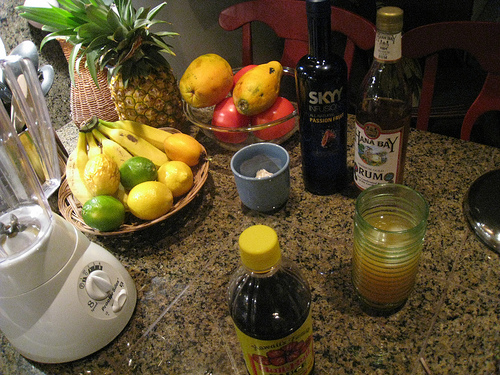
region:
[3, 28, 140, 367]
white blender with clear pitcher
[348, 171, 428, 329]
textured glass of orange juice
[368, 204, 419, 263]
ice cubes in orange juice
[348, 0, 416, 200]
glass bottle of rum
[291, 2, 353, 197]
bottle of SKYY brand vodka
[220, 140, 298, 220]
small cermic coffee mug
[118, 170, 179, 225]
yellow lemon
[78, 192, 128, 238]
green lime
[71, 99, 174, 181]
bunch of yellow bananas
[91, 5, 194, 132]
pineapple with green leaves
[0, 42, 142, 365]
a white electric blender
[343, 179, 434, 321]
a glass with drink and ice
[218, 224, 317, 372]
a plastic bottle with cap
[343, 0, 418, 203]
a bottle of alcohol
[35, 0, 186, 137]
a pineapple fruit with leaves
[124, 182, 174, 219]
a yellow lemon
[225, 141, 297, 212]
a blue ceramic cup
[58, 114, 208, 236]
a wicker basket of fruit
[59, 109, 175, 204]
a bunch of bananas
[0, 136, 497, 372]
a variegated granite countertop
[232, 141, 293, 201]
a small blug mug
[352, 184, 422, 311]
a greenish glass cup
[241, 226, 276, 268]
a yellow plastic top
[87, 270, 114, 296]
a white blender button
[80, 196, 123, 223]
a bright green lime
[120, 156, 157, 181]
a bright green lime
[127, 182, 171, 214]
a bright yellow lemon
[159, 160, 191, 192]
a bright yellow lemon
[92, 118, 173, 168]
a bright yellow banana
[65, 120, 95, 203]
a bright yellow banana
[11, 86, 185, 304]
the blender is empty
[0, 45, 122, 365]
a white blender on a counter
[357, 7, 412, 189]
a bottle of rum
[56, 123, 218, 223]
a wicker basket with bananas, lemons and limes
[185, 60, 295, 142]
a glass bowl with exotic fruits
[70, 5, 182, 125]
a pineapple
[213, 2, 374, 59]
top of a wooden chair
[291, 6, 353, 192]
a black bottle of passion fruit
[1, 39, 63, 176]
a silver pot holding utensils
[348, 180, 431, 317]
a drink in a green glass